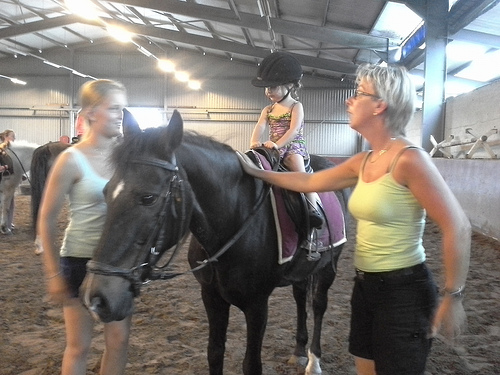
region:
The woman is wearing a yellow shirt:
[342, 147, 441, 266]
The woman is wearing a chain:
[349, 137, 396, 164]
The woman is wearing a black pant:
[341, 261, 446, 369]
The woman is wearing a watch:
[446, 280, 473, 302]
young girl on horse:
[248, 49, 323, 227]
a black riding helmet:
[251, 49, 303, 86]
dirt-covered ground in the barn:
[1, 188, 499, 373]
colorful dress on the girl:
[266, 101, 306, 153]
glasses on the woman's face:
[351, 86, 381, 98]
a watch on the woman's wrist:
[444, 285, 465, 297]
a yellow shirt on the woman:
[346, 144, 428, 274]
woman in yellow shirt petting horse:
[232, 59, 477, 373]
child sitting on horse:
[245, 48, 327, 283]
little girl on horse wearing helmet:
[68, 44, 321, 333]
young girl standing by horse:
[36, 74, 186, 373]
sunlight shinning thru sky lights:
[431, 37, 492, 80]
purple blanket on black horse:
[253, 146, 348, 268]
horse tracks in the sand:
[142, 304, 203, 364]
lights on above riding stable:
[155, 54, 209, 96]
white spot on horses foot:
[302, 344, 324, 374]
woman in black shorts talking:
[250, 64, 475, 374]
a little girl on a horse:
[246, 51, 326, 232]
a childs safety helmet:
[248, 48, 305, 90]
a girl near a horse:
[33, 74, 132, 374]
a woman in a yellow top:
[226, 57, 474, 372]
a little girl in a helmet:
[250, 50, 327, 232]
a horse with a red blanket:
[79, 104, 349, 374]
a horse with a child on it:
[74, 48, 350, 373]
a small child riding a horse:
[79, 48, 351, 373]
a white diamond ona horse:
[108, 177, 127, 202]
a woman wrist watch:
[440, 281, 468, 300]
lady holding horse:
[224, 37, 499, 364]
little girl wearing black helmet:
[234, 43, 319, 112]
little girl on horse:
[227, 48, 352, 232]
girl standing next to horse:
[22, 54, 152, 374]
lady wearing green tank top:
[342, 117, 442, 296]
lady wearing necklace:
[357, 122, 417, 172]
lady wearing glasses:
[350, 57, 400, 132]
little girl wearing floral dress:
[247, 94, 327, 193]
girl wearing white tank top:
[59, 127, 135, 284]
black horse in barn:
[71, 105, 395, 373]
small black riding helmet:
[250, 50, 302, 90]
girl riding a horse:
[246, 48, 324, 232]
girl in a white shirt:
[36, 75, 132, 374]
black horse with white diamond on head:
[77, 105, 349, 374]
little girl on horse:
[64, 42, 370, 372]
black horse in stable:
[78, 125, 396, 370]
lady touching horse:
[84, 52, 482, 370]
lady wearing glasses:
[326, 42, 428, 175]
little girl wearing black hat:
[231, 47, 318, 109]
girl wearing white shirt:
[18, 51, 145, 327]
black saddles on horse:
[241, 116, 346, 247]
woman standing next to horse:
[332, 60, 472, 371]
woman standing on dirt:
[317, 54, 476, 374]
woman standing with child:
[244, 47, 465, 374]